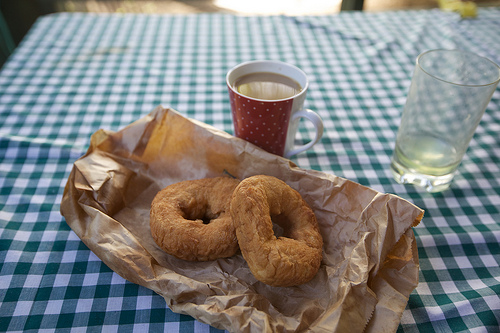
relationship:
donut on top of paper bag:
[229, 173, 325, 288] [58, 104, 425, 332]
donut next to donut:
[229, 173, 325, 288] [149, 175, 243, 259]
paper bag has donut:
[58, 104, 425, 332] [229, 173, 325, 288]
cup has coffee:
[225, 59, 325, 160] [234, 71, 302, 100]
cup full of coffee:
[225, 59, 325, 160] [234, 71, 302, 100]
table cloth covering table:
[0, 5, 499, 331] [0, 4, 500, 332]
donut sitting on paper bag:
[229, 173, 325, 288] [58, 104, 425, 332]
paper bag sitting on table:
[58, 104, 425, 332] [0, 4, 500, 332]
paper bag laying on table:
[58, 104, 425, 332] [0, 4, 500, 332]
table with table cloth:
[0, 4, 500, 332] [0, 5, 499, 331]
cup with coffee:
[225, 59, 325, 160] [234, 71, 302, 100]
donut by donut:
[229, 173, 325, 288] [149, 175, 243, 259]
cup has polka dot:
[225, 59, 325, 160] [260, 120, 267, 126]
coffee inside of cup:
[234, 71, 302, 100] [225, 59, 325, 160]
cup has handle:
[225, 59, 325, 160] [286, 108, 324, 159]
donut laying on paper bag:
[149, 175, 243, 259] [58, 104, 425, 332]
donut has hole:
[229, 173, 325, 288] [269, 209, 296, 241]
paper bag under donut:
[58, 104, 425, 332] [149, 175, 243, 259]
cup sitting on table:
[225, 59, 325, 160] [0, 4, 500, 332]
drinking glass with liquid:
[388, 48, 500, 193] [393, 134, 461, 176]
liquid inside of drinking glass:
[393, 134, 461, 176] [388, 48, 500, 193]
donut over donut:
[229, 173, 325, 288] [149, 175, 243, 259]